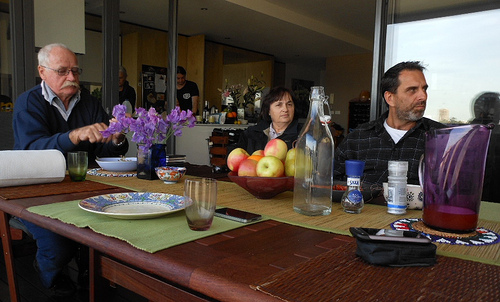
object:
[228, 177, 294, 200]
bowl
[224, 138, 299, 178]
fruit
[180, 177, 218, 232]
glass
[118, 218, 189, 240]
mat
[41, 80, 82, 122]
shirt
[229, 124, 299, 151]
shirt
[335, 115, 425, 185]
shirt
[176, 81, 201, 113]
shirt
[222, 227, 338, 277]
counter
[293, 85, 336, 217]
caraffe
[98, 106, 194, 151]
flowers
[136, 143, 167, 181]
vase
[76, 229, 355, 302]
table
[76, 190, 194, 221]
plate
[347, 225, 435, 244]
cell phone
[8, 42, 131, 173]
man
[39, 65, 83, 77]
glasses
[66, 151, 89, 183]
glass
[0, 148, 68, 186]
towels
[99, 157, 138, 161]
meal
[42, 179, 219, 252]
placesetting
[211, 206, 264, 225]
cell phone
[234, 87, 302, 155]
woman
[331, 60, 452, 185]
man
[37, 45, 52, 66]
hair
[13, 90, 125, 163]
sweater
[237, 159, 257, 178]
apple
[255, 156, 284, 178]
apple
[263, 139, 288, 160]
apple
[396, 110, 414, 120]
beard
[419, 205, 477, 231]
drinks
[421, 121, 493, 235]
pitcher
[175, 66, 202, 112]
person